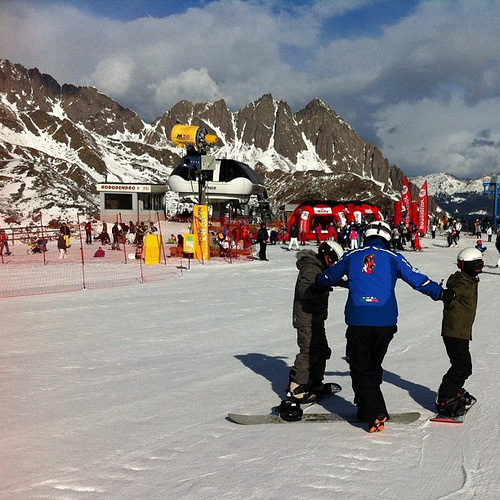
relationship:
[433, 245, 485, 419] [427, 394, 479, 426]
man on snowboard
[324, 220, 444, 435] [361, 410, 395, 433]
man wearing shoes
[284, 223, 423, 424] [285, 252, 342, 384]
man in a suit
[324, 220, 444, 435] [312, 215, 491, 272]
man wearing helmets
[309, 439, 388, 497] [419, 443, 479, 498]
tracks in snow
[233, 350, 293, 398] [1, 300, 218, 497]
shadow on snow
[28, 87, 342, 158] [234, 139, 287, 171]
rocks covered in snow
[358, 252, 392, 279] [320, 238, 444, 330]
logo on back of coat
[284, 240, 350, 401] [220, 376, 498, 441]
man on boards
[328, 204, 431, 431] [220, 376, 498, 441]
man on boards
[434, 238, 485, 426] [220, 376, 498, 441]
man not on boards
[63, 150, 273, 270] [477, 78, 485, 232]
ski lift has pylon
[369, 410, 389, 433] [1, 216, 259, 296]
shoes has fencing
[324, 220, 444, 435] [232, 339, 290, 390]
man has shadow